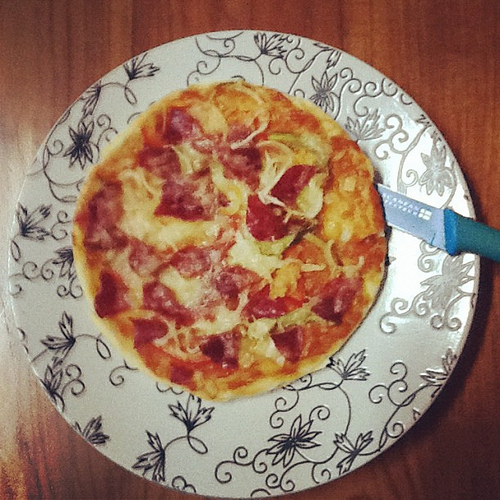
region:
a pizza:
[125, 194, 315, 458]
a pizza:
[181, 362, 289, 447]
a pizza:
[99, 242, 332, 362]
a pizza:
[264, 250, 349, 355]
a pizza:
[232, 232, 360, 403]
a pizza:
[173, 170, 328, 374]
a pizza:
[181, 280, 331, 482]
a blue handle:
[446, 214, 498, 257]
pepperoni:
[271, 172, 304, 203]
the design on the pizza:
[221, 419, 287, 472]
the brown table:
[17, 429, 71, 474]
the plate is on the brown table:
[366, 44, 427, 120]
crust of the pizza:
[243, 378, 283, 397]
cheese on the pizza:
[145, 215, 181, 241]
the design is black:
[416, 142, 448, 200]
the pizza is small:
[94, 112, 384, 364]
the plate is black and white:
[240, 406, 337, 475]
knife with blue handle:
[359, 113, 495, 275]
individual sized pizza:
[71, 76, 392, 397]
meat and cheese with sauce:
[113, 154, 323, 315]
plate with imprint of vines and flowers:
[248, 242, 465, 499]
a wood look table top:
[0, 0, 150, 137]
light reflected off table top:
[1, 60, 35, 468]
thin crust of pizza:
[63, 162, 97, 358]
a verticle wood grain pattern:
[331, 0, 499, 158]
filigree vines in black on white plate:
[175, 337, 421, 499]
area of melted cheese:
[107, 169, 207, 264]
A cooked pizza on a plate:
[67, 81, 413, 415]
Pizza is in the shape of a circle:
[66, 82, 401, 402]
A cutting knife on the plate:
[372, 178, 497, 288]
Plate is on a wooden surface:
[3, 6, 499, 498]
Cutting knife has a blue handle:
[436, 202, 498, 277]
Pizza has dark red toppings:
[65, 75, 407, 398]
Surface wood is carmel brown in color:
[5, 2, 497, 112]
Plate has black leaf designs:
[10, 22, 493, 495]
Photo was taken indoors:
[5, 6, 495, 498]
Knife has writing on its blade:
[379, 186, 440, 233]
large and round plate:
[20, 25, 474, 485]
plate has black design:
[41, 58, 429, 440]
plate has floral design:
[56, 30, 406, 447]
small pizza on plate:
[117, 115, 358, 409]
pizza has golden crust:
[94, 121, 344, 423]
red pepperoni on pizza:
[137, 125, 334, 353]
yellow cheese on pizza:
[162, 117, 369, 381]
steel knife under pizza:
[361, 188, 481, 264]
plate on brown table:
[3, 33, 467, 450]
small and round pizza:
[127, 111, 337, 417]